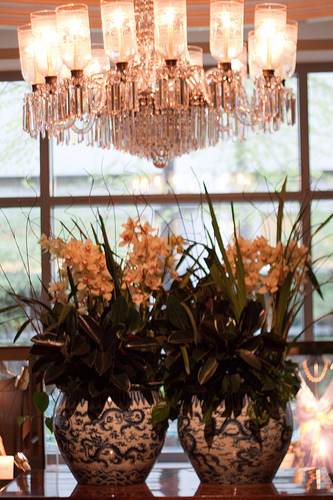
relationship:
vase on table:
[53, 384, 167, 486] [2, 459, 331, 499]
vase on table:
[178, 390, 292, 481] [2, 459, 331, 499]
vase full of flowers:
[53, 384, 167, 486] [7, 171, 179, 408]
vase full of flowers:
[178, 390, 292, 481] [166, 183, 313, 410]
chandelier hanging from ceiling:
[16, 0, 299, 168] [1, 2, 332, 69]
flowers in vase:
[7, 171, 179, 408] [53, 384, 167, 486]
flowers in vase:
[166, 183, 313, 410] [178, 390, 292, 481]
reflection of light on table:
[20, 469, 313, 493] [2, 459, 331, 499]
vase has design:
[53, 384, 167, 486] [59, 402, 162, 481]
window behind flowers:
[1, 68, 328, 439] [7, 171, 179, 408]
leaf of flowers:
[79, 318, 108, 351] [7, 171, 179, 408]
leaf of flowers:
[33, 332, 63, 346] [7, 171, 179, 408]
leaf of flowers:
[89, 376, 109, 397] [7, 171, 179, 408]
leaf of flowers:
[127, 340, 157, 353] [7, 171, 179, 408]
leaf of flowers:
[45, 362, 66, 381] [7, 171, 179, 408]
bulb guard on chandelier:
[156, 2, 187, 62] [16, 0, 299, 168]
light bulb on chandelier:
[109, 8, 127, 41] [16, 0, 299, 168]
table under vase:
[2, 459, 331, 499] [53, 384, 167, 486]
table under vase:
[2, 459, 331, 499] [178, 390, 292, 481]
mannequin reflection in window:
[288, 349, 332, 472] [1, 68, 328, 439]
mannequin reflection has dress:
[288, 349, 332, 472] [293, 372, 332, 469]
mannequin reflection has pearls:
[288, 349, 332, 472] [300, 358, 328, 381]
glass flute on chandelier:
[210, 2, 244, 62] [16, 0, 299, 168]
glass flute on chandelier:
[254, 5, 286, 72] [16, 0, 299, 168]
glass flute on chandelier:
[57, 2, 95, 73] [16, 0, 299, 168]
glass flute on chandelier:
[30, 7, 64, 82] [16, 0, 299, 168]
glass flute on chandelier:
[17, 22, 47, 92] [16, 0, 299, 168]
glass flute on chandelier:
[283, 18, 299, 82] [16, 0, 299, 168]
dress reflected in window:
[293, 372, 332, 469] [1, 68, 328, 439]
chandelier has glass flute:
[16, 0, 299, 168] [210, 2, 244, 62]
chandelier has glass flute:
[16, 0, 299, 168] [254, 5, 286, 72]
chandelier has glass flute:
[16, 0, 299, 168] [283, 18, 299, 82]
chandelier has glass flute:
[16, 0, 299, 168] [57, 2, 95, 73]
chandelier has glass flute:
[16, 0, 299, 168] [30, 7, 64, 82]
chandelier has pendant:
[16, 0, 299, 168] [94, 116, 108, 149]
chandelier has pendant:
[16, 0, 299, 168] [110, 115, 124, 143]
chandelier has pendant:
[16, 0, 299, 168] [206, 109, 219, 145]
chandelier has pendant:
[16, 0, 299, 168] [197, 111, 211, 147]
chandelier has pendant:
[16, 0, 299, 168] [170, 114, 186, 156]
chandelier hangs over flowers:
[16, 0, 299, 168] [7, 171, 179, 408]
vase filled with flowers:
[53, 384, 167, 486] [7, 171, 179, 408]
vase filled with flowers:
[178, 390, 292, 481] [7, 171, 179, 408]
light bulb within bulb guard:
[109, 8, 127, 41] [102, 2, 135, 65]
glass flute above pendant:
[210, 2, 244, 62] [206, 109, 219, 145]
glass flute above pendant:
[254, 5, 286, 72] [197, 111, 211, 147]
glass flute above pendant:
[283, 18, 299, 82] [206, 109, 219, 145]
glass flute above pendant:
[57, 2, 95, 73] [110, 115, 124, 143]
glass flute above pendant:
[30, 7, 64, 82] [94, 116, 108, 149]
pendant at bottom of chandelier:
[170, 114, 186, 156] [16, 0, 299, 168]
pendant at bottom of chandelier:
[206, 109, 219, 145] [16, 0, 299, 168]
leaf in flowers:
[200, 180, 236, 290] [166, 183, 313, 410]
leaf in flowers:
[272, 174, 290, 249] [166, 183, 313, 410]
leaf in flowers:
[287, 185, 323, 260] [7, 171, 179, 408]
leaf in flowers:
[13, 289, 61, 319] [7, 171, 179, 408]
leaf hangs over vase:
[92, 208, 133, 312] [53, 384, 167, 486]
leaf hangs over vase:
[272, 174, 290, 249] [178, 390, 292, 481]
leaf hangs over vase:
[200, 180, 236, 290] [178, 390, 292, 481]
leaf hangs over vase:
[287, 185, 323, 260] [178, 390, 292, 481]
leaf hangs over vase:
[163, 178, 206, 280] [53, 384, 167, 486]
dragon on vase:
[81, 438, 151, 463] [53, 384, 167, 486]